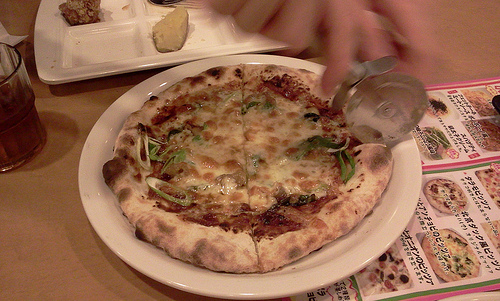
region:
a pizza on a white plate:
[76, 50, 423, 293]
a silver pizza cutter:
[341, 55, 428, 145]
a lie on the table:
[0, 42, 47, 172]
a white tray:
[36, 3, 329, 84]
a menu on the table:
[423, 87, 498, 289]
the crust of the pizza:
[144, 206, 264, 276]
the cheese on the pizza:
[201, 127, 288, 190]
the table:
[6, 180, 76, 290]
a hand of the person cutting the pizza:
[231, 3, 455, 91]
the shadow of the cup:
[31, 115, 77, 170]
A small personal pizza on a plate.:
[75, 50, 420, 294]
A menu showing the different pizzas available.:
[416, 155, 498, 265]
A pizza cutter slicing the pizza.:
[338, 55, 438, 152]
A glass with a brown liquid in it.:
[0, 35, 47, 185]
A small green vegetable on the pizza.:
[148, 139, 193, 172]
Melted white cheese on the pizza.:
[221, 115, 284, 165]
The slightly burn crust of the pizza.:
[100, 155, 135, 210]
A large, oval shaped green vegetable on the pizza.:
[144, 174, 198, 208]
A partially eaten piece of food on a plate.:
[148, 3, 195, 56]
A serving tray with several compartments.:
[35, 4, 287, 79]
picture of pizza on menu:
[423, 227, 486, 286]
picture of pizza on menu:
[373, 260, 416, 297]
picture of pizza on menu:
[430, 170, 466, 215]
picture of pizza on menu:
[481, 164, 499, 199]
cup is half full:
[0, 60, 40, 161]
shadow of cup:
[30, 113, 83, 169]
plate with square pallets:
[49, 6, 229, 68]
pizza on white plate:
[108, 66, 410, 287]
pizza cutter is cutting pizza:
[345, 39, 425, 144]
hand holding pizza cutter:
[258, 2, 424, 137]